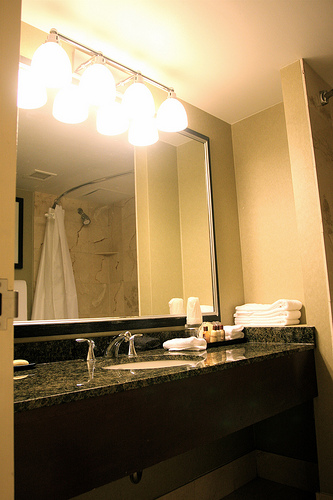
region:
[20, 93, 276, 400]
mirror above a bathroom counter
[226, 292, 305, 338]
folded towels beside wall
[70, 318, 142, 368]
silver faucets and spigot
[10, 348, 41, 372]
tan soap in black dish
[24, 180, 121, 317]
white shower curtain and rod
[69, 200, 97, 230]
shower-head nozzle on wall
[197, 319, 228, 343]
miniature bottles of toiletries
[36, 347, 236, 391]
dark stone surface of counter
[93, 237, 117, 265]
small shelf fitted into corner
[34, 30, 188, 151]
bright white lights over mirror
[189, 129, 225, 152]
silver edge of mirror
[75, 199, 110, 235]
silver shower on wall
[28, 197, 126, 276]
white shower curtain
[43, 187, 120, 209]
silver shower rod in bathroom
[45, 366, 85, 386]
black and brown counter top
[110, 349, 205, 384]
large white sink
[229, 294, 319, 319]
stack of large white towels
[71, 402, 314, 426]
dark brown doors in bathroom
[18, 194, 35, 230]
brown edge on wall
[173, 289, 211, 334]
white air freshener on counter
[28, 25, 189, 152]
lights are above the sink mirror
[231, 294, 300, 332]
stack of washcloths on the sink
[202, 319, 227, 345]
assortment of sample toiletries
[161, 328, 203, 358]
washcloth beside the sink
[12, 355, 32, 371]
soap on a dish on the sink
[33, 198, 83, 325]
shower curtain hanging from rod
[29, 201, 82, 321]
shower curtain is white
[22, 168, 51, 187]
air vent above shower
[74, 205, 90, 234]
shower head hanging on wall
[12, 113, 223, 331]
mirror above the sink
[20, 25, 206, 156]
Track lighting four mirrored eight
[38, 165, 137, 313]
Other side room mirror shower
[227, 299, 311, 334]
Stacked white bath towels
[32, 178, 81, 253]
Shower curtain extend wide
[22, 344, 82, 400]
Black brown marble counter top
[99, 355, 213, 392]
One round sink basin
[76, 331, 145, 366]
Silver hot cold faucets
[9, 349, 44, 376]
Soap dish handy needed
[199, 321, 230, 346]
Toiletries tray with washcloths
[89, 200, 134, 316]
Shower stall marbelized walls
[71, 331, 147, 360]
chrome fixtures on the sink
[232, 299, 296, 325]
white towel folded on the counter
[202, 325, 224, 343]
bottle of shampoo on a tray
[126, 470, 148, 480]
a metal pipe under the counter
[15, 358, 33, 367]
a bar of soap on a dish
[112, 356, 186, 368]
a white porcelain sink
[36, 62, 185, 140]
a row of white lights above the sink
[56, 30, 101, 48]
silver bar supporting lights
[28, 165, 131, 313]
a reflection of the room in the mirror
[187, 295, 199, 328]
a stack of white plastic cups